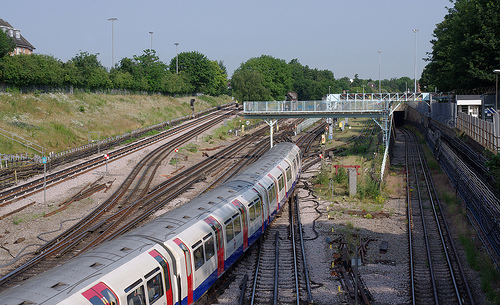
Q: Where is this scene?
A: Railway.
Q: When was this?
A: Daytime.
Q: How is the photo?
A: Clear.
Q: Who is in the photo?
A: No one.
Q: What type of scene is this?
A: Outdoor.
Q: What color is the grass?
A: Green.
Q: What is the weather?
A: Sunny.